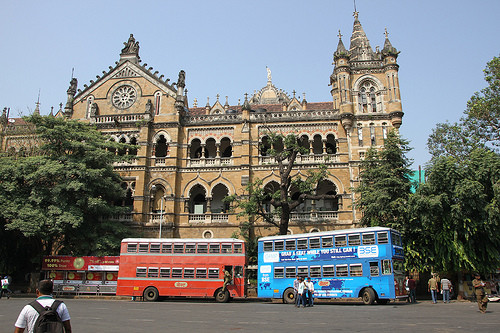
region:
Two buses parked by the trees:
[117, 228, 409, 304]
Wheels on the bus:
[143, 286, 228, 301]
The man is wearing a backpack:
[26, 299, 68, 331]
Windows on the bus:
[123, 242, 245, 254]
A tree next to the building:
[227, 126, 323, 236]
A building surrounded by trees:
[1, 1, 403, 290]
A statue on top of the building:
[263, 64, 272, 79]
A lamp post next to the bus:
[158, 193, 173, 238]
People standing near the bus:
[295, 277, 315, 304]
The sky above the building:
[0, 2, 496, 192]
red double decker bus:
[115, 233, 247, 302]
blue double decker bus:
[255, 224, 408, 304]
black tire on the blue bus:
[358, 285, 376, 306]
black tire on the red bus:
[141, 284, 159, 301]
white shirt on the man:
[12, 291, 69, 331]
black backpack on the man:
[27, 297, 66, 332]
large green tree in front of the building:
[0, 113, 135, 265]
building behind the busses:
[0, 0, 405, 238]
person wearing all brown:
[472, 276, 491, 311]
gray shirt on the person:
[438, 277, 453, 292]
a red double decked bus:
[112, 237, 252, 304]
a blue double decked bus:
[252, 223, 417, 305]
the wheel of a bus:
[139, 282, 160, 302]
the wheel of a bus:
[209, 285, 231, 305]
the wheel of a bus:
[280, 287, 301, 307]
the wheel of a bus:
[355, 284, 377, 311]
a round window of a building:
[107, 81, 149, 109]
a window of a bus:
[260, 240, 275, 253]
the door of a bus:
[222, 263, 246, 303]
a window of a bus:
[134, 265, 147, 281]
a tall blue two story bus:
[255, 211, 415, 312]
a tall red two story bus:
[117, 241, 238, 299]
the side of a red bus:
[117, 228, 245, 310]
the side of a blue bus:
[245, 229, 400, 303]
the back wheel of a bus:
[134, 278, 156, 305]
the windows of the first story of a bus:
[262, 261, 369, 281]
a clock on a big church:
[114, 81, 132, 113]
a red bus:
[115, 237, 248, 295]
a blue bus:
[261, 235, 387, 297]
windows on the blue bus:
[262, 240, 387, 250]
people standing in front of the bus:
[286, 267, 316, 299]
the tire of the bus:
[142, 285, 154, 295]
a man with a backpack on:
[11, 275, 86, 326]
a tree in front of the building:
[1, 106, 107, 256]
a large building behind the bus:
[20, 30, 416, 245]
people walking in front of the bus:
[425, 270, 486, 320]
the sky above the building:
[20, 10, 291, 81]